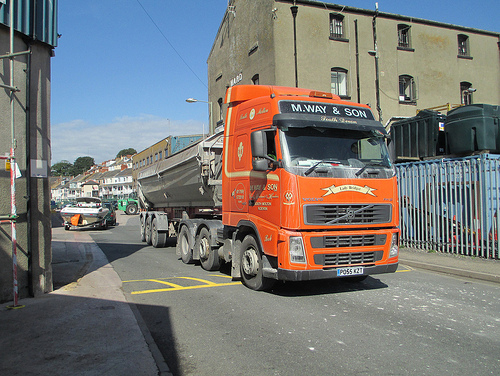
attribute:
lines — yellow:
[119, 273, 241, 295]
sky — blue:
[59, 18, 151, 82]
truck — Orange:
[132, 82, 425, 302]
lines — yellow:
[125, 266, 240, 300]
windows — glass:
[328, 12, 473, 107]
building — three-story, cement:
[206, 0, 498, 135]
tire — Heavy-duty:
[236, 230, 266, 296]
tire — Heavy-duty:
[193, 223, 218, 270]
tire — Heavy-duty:
[173, 220, 196, 268]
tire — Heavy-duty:
[146, 213, 169, 252]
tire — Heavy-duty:
[119, 197, 141, 227]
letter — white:
[314, 102, 322, 114]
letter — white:
[290, 100, 302, 112]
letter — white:
[344, 105, 351, 116]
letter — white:
[352, 109, 358, 116]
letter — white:
[358, 107, 367, 117]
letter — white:
[305, 103, 315, 111]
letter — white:
[344, 106, 351, 115]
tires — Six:
[135, 208, 267, 294]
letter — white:
[294, 101, 324, 114]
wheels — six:
[136, 208, 266, 290]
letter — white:
[343, 108, 352, 118]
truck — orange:
[127, 77, 410, 297]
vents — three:
[301, 197, 395, 272]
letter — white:
[304, 102, 314, 111]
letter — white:
[313, 102, 323, 112]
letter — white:
[320, 105, 327, 112]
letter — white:
[332, 106, 340, 113]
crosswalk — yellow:
[113, 258, 438, 302]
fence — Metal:
[395, 154, 494, 270]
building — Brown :
[199, 1, 496, 151]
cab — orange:
[220, 86, 402, 289]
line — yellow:
[176, 273, 215, 284]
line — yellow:
[208, 270, 232, 279]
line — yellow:
[118, 273, 184, 282]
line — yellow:
[145, 277, 182, 287]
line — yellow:
[174, 272, 214, 282]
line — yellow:
[206, 270, 234, 276]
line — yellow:
[130, 279, 240, 293]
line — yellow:
[120, 274, 183, 283]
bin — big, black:
[442, 100, 484, 159]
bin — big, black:
[383, 109, 443, 161]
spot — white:
[308, 345, 316, 350]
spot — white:
[336, 338, 346, 346]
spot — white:
[377, 303, 385, 311]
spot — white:
[445, 325, 454, 333]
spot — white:
[390, 293, 399, 297]